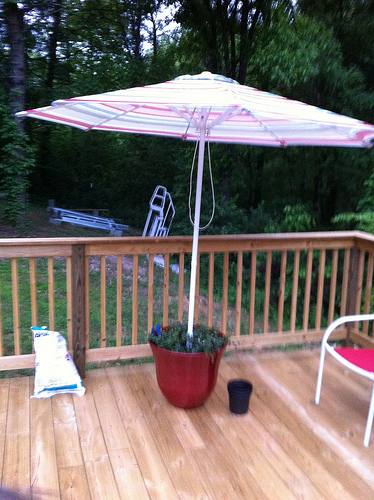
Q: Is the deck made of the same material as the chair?
A: No, the deck is made of wood and the chair is made of metal.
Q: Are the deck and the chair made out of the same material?
A: No, the deck is made of wood and the chair is made of metal.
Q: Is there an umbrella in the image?
A: Yes, there is an umbrella.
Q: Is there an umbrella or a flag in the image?
A: Yes, there is an umbrella.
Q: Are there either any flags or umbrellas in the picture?
A: Yes, there is an umbrella.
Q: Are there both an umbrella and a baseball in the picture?
A: No, there is an umbrella but no baseballs.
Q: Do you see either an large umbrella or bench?
A: Yes, there is a large umbrella.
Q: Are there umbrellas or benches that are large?
A: Yes, the umbrella is large.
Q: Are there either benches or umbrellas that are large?
A: Yes, the umbrella is large.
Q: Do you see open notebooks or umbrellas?
A: Yes, there is an open umbrella.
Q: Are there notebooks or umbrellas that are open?
A: Yes, the umbrella is open.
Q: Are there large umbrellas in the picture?
A: Yes, there is a large umbrella.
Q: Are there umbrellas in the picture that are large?
A: Yes, there is an umbrella that is large.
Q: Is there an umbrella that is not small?
A: Yes, there is a large umbrella.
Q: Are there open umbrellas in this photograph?
A: Yes, there is an open umbrella.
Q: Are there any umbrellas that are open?
A: Yes, there is an umbrella that is open.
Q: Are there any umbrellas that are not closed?
A: Yes, there is a open umbrella.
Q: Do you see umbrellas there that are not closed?
A: Yes, there is a open umbrella.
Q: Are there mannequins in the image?
A: No, there are no mannequins.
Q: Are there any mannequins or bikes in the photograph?
A: No, there are no mannequins or bikes.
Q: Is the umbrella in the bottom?
A: No, the umbrella is in the top of the image.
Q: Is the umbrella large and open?
A: Yes, the umbrella is large and open.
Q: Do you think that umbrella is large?
A: Yes, the umbrella is large.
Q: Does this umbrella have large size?
A: Yes, the umbrella is large.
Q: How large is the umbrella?
A: The umbrella is large.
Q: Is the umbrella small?
A: No, the umbrella is large.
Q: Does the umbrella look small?
A: No, the umbrella is large.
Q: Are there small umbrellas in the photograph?
A: No, there is an umbrella but it is large.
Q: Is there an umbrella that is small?
A: No, there is an umbrella but it is large.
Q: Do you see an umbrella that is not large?
A: No, there is an umbrella but it is large.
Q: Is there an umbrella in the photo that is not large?
A: No, there is an umbrella but it is large.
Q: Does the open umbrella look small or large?
A: The umbrella is large.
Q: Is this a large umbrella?
A: Yes, this is a large umbrella.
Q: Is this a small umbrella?
A: No, this is a large umbrella.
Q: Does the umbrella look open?
A: Yes, the umbrella is open.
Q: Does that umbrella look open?
A: Yes, the umbrella is open.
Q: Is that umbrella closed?
A: No, the umbrella is open.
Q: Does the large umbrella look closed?
A: No, the umbrella is open.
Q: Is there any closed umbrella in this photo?
A: No, there is an umbrella but it is open.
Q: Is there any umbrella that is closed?
A: No, there is an umbrella but it is open.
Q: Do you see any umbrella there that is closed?
A: No, there is an umbrella but it is open.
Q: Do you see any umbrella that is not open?
A: No, there is an umbrella but it is open.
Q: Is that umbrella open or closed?
A: The umbrella is open.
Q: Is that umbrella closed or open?
A: The umbrella is open.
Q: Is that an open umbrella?
A: Yes, that is an open umbrella.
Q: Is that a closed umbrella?
A: No, that is an open umbrella.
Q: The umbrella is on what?
A: The umbrella is on the deck.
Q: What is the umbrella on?
A: The umbrella is on the deck.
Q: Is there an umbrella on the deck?
A: Yes, there is an umbrella on the deck.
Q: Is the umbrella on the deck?
A: Yes, the umbrella is on the deck.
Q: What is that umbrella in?
A: The umbrella is in the planter.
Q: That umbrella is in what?
A: The umbrella is in the planter.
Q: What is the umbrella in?
A: The umbrella is in the planter.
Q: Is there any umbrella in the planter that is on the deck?
A: Yes, there is an umbrella in the planter.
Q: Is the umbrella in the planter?
A: Yes, the umbrella is in the planter.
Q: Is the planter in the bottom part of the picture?
A: Yes, the planter is in the bottom of the image.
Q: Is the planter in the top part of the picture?
A: No, the planter is in the bottom of the image.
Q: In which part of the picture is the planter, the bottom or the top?
A: The planter is in the bottom of the image.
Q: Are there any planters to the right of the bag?
A: Yes, there is a planter to the right of the bag.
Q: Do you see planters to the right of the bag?
A: Yes, there is a planter to the right of the bag.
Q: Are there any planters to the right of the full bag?
A: Yes, there is a planter to the right of the bag.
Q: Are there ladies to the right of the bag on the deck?
A: No, there is a planter to the right of the bag.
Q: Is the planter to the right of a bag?
A: Yes, the planter is to the right of a bag.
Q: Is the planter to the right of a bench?
A: No, the planter is to the right of a bag.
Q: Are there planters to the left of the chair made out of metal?
A: Yes, there is a planter to the left of the chair.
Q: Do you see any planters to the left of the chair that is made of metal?
A: Yes, there is a planter to the left of the chair.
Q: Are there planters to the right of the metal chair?
A: No, the planter is to the left of the chair.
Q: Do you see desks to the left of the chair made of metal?
A: No, there is a planter to the left of the chair.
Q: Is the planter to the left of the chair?
A: Yes, the planter is to the left of the chair.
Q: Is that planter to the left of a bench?
A: No, the planter is to the left of the chair.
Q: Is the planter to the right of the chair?
A: No, the planter is to the left of the chair.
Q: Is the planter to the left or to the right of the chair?
A: The planter is to the left of the chair.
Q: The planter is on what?
A: The planter is on the deck.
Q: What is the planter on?
A: The planter is on the deck.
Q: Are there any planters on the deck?
A: Yes, there is a planter on the deck.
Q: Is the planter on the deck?
A: Yes, the planter is on the deck.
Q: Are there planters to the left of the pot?
A: Yes, there is a planter to the left of the pot.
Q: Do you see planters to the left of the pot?
A: Yes, there is a planter to the left of the pot.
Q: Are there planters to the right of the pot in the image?
A: No, the planter is to the left of the pot.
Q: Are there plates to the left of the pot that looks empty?
A: No, there is a planter to the left of the pot.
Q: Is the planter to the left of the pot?
A: Yes, the planter is to the left of the pot.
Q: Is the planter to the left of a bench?
A: No, the planter is to the left of the pot.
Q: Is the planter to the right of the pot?
A: No, the planter is to the left of the pot.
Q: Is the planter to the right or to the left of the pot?
A: The planter is to the left of the pot.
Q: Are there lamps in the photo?
A: No, there are no lamps.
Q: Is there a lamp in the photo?
A: No, there are no lamps.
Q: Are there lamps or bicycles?
A: No, there are no lamps or bicycles.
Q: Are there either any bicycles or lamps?
A: No, there are no lamps or bicycles.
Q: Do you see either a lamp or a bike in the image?
A: No, there are no lamps or bikes.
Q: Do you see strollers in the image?
A: No, there are no strollers.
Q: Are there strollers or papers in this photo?
A: No, there are no strollers or papers.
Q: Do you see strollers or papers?
A: No, there are no strollers or papers.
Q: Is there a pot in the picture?
A: Yes, there is a pot.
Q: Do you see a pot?
A: Yes, there is a pot.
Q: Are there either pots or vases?
A: Yes, there is a pot.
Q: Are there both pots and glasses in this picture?
A: No, there is a pot but no glasses.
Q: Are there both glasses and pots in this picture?
A: No, there is a pot but no glasses.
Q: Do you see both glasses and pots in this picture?
A: No, there is a pot but no glasses.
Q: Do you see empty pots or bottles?
A: Yes, there is an empty pot.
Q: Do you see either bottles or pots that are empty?
A: Yes, the pot is empty.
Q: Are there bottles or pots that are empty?
A: Yes, the pot is empty.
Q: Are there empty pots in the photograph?
A: Yes, there is an empty pot.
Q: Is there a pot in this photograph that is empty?
A: Yes, there is a pot that is empty.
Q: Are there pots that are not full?
A: Yes, there is a empty pot.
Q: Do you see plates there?
A: No, there are no plates.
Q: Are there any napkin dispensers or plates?
A: No, there are no plates or napkin dispensers.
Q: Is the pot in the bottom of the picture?
A: Yes, the pot is in the bottom of the image.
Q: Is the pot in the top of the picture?
A: No, the pot is in the bottom of the image.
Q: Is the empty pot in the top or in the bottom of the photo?
A: The pot is in the bottom of the image.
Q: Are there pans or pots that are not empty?
A: No, there is a pot but it is empty.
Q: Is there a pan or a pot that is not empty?
A: No, there is a pot but it is empty.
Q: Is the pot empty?
A: Yes, the pot is empty.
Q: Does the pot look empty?
A: Yes, the pot is empty.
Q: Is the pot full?
A: No, the pot is empty.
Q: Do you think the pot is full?
A: No, the pot is empty.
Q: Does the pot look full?
A: No, the pot is empty.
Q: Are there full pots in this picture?
A: No, there is a pot but it is empty.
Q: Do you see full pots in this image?
A: No, there is a pot but it is empty.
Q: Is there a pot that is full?
A: No, there is a pot but it is empty.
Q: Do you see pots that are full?
A: No, there is a pot but it is empty.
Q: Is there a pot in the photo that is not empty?
A: No, there is a pot but it is empty.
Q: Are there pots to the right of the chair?
A: No, the pot is to the left of the chair.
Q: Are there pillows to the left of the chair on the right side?
A: No, there is a pot to the left of the chair.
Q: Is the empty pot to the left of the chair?
A: Yes, the pot is to the left of the chair.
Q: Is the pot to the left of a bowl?
A: No, the pot is to the left of the chair.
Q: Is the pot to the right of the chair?
A: No, the pot is to the left of the chair.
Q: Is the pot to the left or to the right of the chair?
A: The pot is to the left of the chair.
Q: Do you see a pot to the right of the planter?
A: Yes, there is a pot to the right of the planter.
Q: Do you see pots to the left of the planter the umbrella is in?
A: No, the pot is to the right of the planter.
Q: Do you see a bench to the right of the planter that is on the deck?
A: No, there is a pot to the right of the planter.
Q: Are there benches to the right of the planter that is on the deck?
A: No, there is a pot to the right of the planter.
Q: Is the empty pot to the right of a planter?
A: Yes, the pot is to the right of a planter.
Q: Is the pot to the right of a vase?
A: No, the pot is to the right of a planter.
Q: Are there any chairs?
A: Yes, there is a chair.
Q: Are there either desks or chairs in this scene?
A: Yes, there is a chair.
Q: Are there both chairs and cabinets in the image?
A: No, there is a chair but no cabinets.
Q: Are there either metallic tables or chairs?
A: Yes, there is a metal chair.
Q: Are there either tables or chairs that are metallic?
A: Yes, the chair is metallic.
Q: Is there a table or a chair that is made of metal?
A: Yes, the chair is made of metal.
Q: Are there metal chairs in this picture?
A: Yes, there is a metal chair.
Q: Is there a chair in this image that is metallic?
A: Yes, there is a chair that is metallic.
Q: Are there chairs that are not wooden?
A: Yes, there is a metallic chair.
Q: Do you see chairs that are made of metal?
A: Yes, there is a chair that is made of metal.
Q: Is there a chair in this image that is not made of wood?
A: Yes, there is a chair that is made of metal.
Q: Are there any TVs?
A: No, there are no tvs.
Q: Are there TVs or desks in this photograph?
A: No, there are no TVs or desks.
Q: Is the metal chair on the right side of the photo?
A: Yes, the chair is on the right of the image.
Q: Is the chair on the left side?
A: No, the chair is on the right of the image.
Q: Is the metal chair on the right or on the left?
A: The chair is on the right of the image.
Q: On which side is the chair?
A: The chair is on the right of the image.